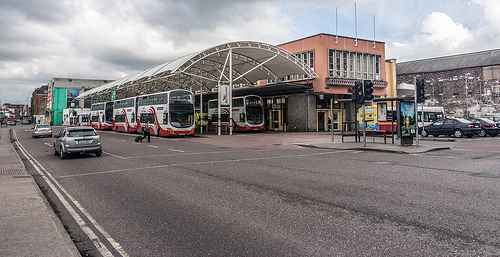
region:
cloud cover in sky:
[2, 2, 499, 103]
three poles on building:
[321, 2, 383, 79]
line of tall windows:
[323, 45, 383, 80]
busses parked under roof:
[76, 42, 311, 137]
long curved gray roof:
[80, 39, 315, 99]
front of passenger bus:
[165, 87, 195, 129]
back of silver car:
[58, 126, 102, 154]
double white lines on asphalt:
[8, 125, 128, 255]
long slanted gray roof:
[393, 47, 498, 74]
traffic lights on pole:
[349, 79, 375, 147]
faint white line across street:
[106, 163, 258, 173]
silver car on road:
[52, 124, 111, 159]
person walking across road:
[130, 118, 160, 153]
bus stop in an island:
[332, 85, 427, 145]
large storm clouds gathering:
[84, 11, 201, 27]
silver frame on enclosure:
[210, 45, 240, 126]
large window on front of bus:
[158, 83, 205, 136]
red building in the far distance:
[6, 95, 28, 123]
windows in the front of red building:
[321, 32, 396, 95]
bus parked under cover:
[207, 84, 283, 128]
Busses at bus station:
[68, 93, 275, 149]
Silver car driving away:
[54, 130, 114, 157]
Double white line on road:
[25, 153, 121, 255]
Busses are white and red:
[85, 105, 205, 128]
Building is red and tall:
[298, 33, 402, 99]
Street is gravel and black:
[112, 146, 482, 252]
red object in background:
[373, 116, 404, 138]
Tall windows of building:
[333, 47, 379, 80]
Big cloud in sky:
[404, 5, 475, 60]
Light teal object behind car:
[48, 83, 68, 130]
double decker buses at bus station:
[90, 88, 313, 134]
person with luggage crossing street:
[124, 116, 158, 142]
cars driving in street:
[25, 116, 108, 161]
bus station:
[79, 29, 396, 140]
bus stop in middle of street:
[335, 74, 421, 153]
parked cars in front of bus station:
[415, 90, 499, 141]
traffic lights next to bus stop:
[349, 67, 427, 151]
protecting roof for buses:
[70, 36, 320, 138]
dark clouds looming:
[3, 4, 281, 109]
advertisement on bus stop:
[395, 92, 419, 146]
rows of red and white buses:
[69, 90, 264, 135]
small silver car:
[54, 125, 104, 155]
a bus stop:
[337, 101, 415, 148]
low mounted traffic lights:
[347, 78, 375, 103]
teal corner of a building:
[50, 87, 67, 121]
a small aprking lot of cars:
[412, 103, 499, 149]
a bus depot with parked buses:
[77, 31, 386, 133]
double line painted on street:
[5, 120, 129, 253]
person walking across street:
[132, 120, 154, 143]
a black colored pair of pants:
[137, 129, 153, 143]